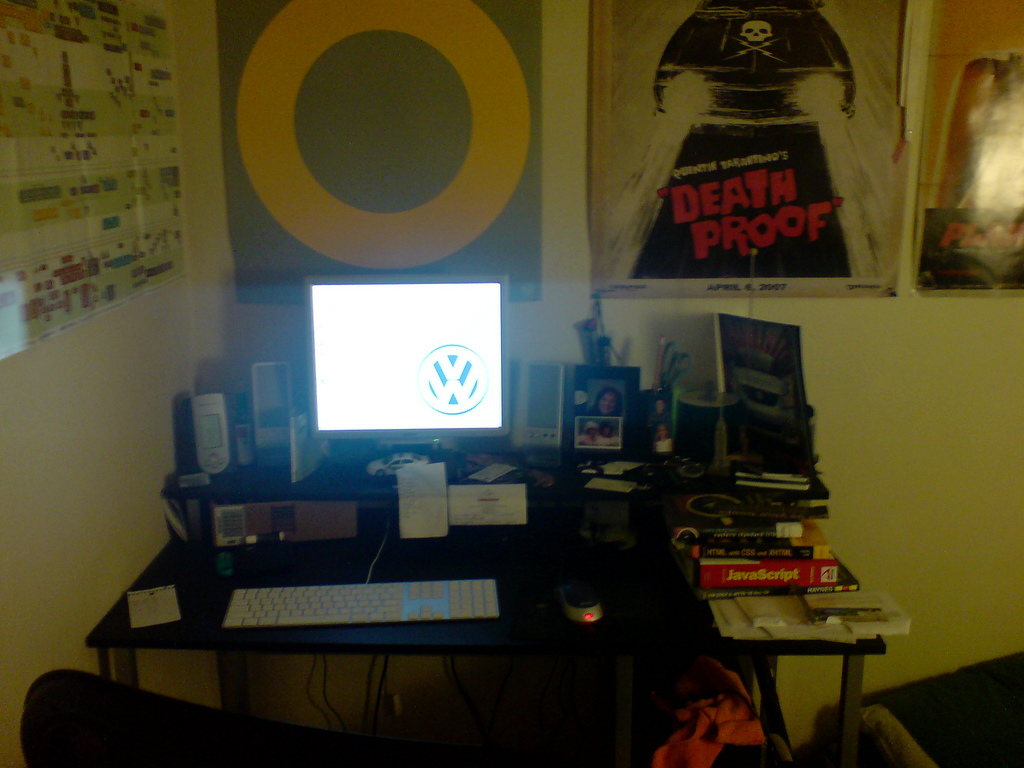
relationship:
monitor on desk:
[302, 271, 509, 453] [76, 459, 943, 764]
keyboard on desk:
[210, 560, 507, 632] [76, 459, 943, 764]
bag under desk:
[644, 648, 776, 765] [76, 459, 943, 764]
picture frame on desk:
[559, 351, 644, 468] [75, 420, 951, 760]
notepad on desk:
[115, 569, 191, 636] [76, 459, 943, 764]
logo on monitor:
[415, 335, 493, 418] [292, 268, 515, 448]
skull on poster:
[726, 5, 783, 68] [566, 0, 917, 310]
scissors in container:
[650, 325, 694, 403] [639, 374, 692, 463]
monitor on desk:
[298, 266, 517, 472] [76, 458, 918, 763]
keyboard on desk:
[219, 579, 501, 632] [76, 458, 918, 763]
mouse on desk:
[549, 573, 608, 626] [76, 458, 918, 763]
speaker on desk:
[183, 381, 238, 485] [76, 458, 918, 763]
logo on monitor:
[414, 344, 493, 416] [302, 271, 509, 453]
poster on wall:
[203, 1, 560, 324] [171, 5, 990, 764]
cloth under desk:
[626, 657, 776, 764] [76, 458, 918, 763]